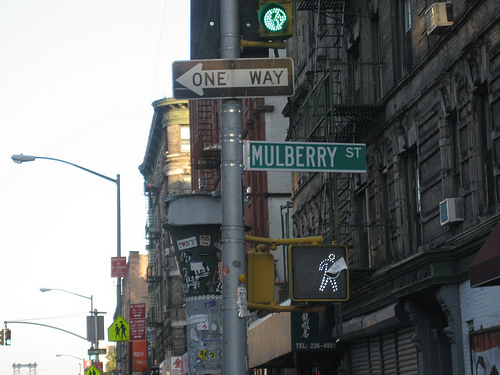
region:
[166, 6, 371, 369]
pole with traffic lights, street sign and traffic sign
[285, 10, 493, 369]
dark gray building with black fire escape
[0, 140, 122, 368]
poles with extended streetlights and traffic light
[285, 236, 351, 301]
outline of walker in lights with sticker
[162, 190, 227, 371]
funnel-shaped structure filled with stickers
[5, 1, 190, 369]
bright blue sky to side of buildings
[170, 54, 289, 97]
white and black sign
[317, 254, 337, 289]
the light is on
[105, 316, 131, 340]
yellow and black sign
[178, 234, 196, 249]
sticker on the metal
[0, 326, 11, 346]
traffic light above ground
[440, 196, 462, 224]
air conditioner on wall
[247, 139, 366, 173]
green and white sign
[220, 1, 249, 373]
pole made of metal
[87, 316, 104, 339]
back of a sign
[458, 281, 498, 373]
white paint on wall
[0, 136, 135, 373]
the street light on a pole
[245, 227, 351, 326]
a yellow traffic light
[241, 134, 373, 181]
a green sign on a pole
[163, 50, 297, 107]
an arrow color white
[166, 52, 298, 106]
arrow says One Way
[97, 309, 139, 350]
a pedestrian sign color green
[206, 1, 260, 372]
the pole is color gray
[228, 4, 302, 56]
a yellow sign on gray pole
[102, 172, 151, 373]
several signs on a pole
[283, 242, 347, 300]
A walk sign on a pole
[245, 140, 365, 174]
A green sign with white letters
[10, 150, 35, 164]
A street light on a pole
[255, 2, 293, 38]
A green traffic light on a pole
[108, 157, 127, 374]
A tall pole with a street light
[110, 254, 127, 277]
A red sign on a pole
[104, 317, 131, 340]
A yellow sign on a pole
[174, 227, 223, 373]
Many stickers on a post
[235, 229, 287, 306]
A yellow bracket on a pole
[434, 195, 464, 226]
Air conditioner sticking out of a building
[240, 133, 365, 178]
white and green street sign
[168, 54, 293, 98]
black and white one way sign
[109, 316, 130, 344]
yellow sign with black outline of people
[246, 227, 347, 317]
signals for the pedestrian crossing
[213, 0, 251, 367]
metal pole signs are attached to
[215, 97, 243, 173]
brackets attaching signs to pole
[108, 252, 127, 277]
red sign with white lettering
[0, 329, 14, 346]
two traffic signals in the distance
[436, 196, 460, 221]
a/c unit hanging out the window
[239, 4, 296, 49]
traffic signal showing green light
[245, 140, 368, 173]
A green sign on a gray pole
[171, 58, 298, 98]
A black sign on a pole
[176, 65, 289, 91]
A white arrow on a black sign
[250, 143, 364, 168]
White letters on a green sign